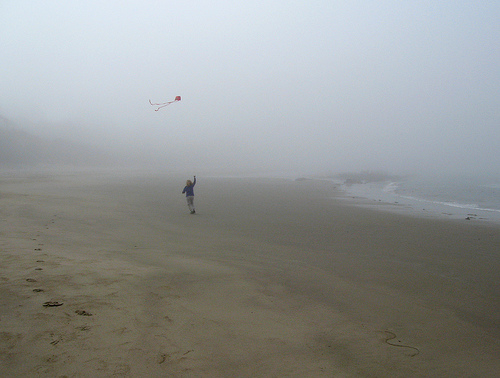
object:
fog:
[4, 4, 492, 182]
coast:
[275, 158, 498, 216]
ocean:
[349, 140, 499, 212]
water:
[401, 175, 499, 214]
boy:
[182, 175, 198, 214]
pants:
[186, 195, 196, 211]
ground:
[0, 178, 500, 372]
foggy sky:
[3, 0, 497, 177]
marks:
[23, 234, 97, 323]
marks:
[153, 341, 201, 370]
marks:
[375, 323, 421, 356]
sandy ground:
[2, 130, 494, 375]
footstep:
[33, 247, 42, 251]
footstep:
[43, 299, 64, 308]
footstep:
[32, 287, 45, 293]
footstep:
[25, 277, 37, 283]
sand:
[0, 164, 497, 374]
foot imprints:
[72, 307, 96, 319]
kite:
[147, 91, 183, 114]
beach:
[6, 162, 499, 378]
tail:
[148, 96, 171, 113]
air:
[1, 6, 500, 378]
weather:
[0, 0, 499, 321]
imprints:
[38, 242, 44, 246]